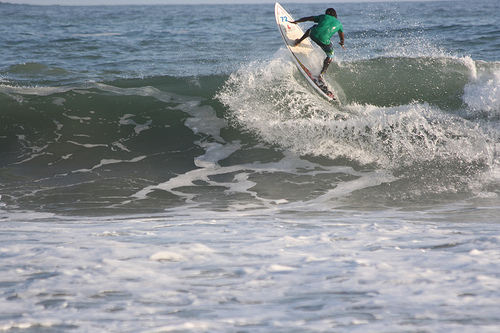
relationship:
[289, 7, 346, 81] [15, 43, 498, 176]
body surfing wave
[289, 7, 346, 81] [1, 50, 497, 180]
body surfing wave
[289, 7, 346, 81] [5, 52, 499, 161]
body surfing wave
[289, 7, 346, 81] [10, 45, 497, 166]
body surfing wave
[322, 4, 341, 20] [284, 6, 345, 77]
head of person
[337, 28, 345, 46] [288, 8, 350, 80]
arm of person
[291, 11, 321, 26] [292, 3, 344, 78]
arm of person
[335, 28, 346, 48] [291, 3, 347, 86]
arm of person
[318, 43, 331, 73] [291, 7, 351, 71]
leg of person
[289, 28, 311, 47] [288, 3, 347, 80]
leg of person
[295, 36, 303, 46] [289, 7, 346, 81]
foot of body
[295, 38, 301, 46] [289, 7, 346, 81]
foot of body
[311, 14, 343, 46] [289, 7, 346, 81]
body of body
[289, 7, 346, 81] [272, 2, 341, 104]
body on board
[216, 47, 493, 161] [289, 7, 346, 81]
wake around body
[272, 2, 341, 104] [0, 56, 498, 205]
board crossing wave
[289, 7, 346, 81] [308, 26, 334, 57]
body has shorts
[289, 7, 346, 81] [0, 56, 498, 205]
body surfing wave